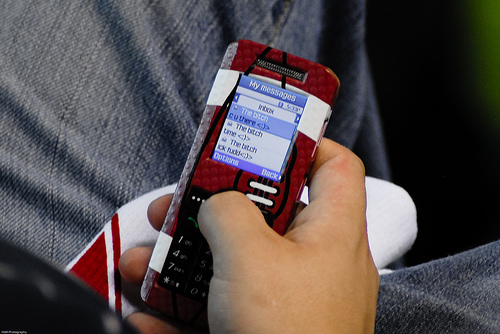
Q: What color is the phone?
A: Red.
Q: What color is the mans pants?
A: Blue.